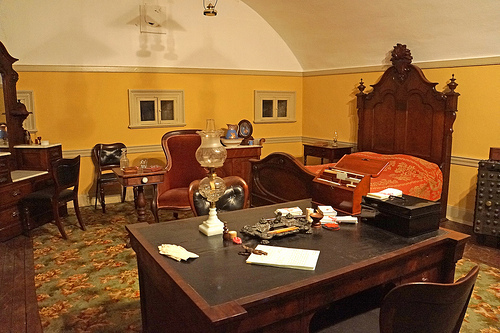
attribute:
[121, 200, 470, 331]
desk — inlaid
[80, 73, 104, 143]
wall — yellow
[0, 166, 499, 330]
carpet — gold, green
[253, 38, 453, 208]
bed — red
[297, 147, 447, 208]
bedspread — orange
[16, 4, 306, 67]
wall — white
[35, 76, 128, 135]
wall — dark yellow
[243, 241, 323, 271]
paper — white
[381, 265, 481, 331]
chair — brown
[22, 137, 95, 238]
furniture — wood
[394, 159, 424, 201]
blanket — red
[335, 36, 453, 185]
headboard — large, brown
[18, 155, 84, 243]
chair — brown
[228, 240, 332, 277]
papers — white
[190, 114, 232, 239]
lamp — clear